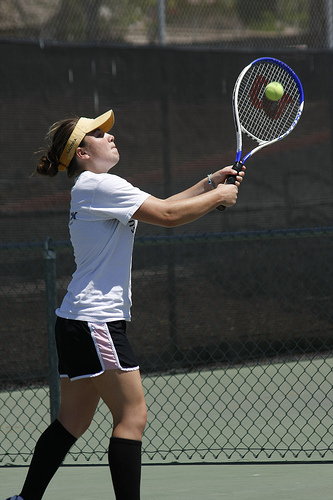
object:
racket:
[215, 56, 305, 212]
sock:
[104, 435, 143, 499]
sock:
[16, 416, 78, 495]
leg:
[91, 350, 148, 500]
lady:
[2, 109, 247, 500]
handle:
[216, 161, 243, 211]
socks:
[19, 417, 142, 499]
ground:
[0, 0, 333, 500]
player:
[8, 109, 246, 500]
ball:
[264, 79, 284, 101]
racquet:
[215, 55, 304, 213]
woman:
[3, 108, 247, 500]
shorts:
[53, 312, 142, 383]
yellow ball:
[264, 79, 285, 102]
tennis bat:
[215, 53, 308, 212]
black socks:
[106, 432, 142, 497]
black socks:
[19, 419, 76, 500]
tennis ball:
[264, 79, 285, 102]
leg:
[88, 346, 148, 500]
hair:
[35, 116, 78, 180]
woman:
[0, 118, 246, 500]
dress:
[53, 169, 150, 382]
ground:
[0, 349, 330, 497]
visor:
[57, 108, 114, 173]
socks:
[106, 433, 143, 499]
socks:
[14, 418, 76, 500]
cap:
[57, 108, 115, 171]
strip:
[85, 320, 123, 373]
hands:
[214, 164, 246, 209]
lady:
[6, 108, 246, 500]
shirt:
[54, 169, 152, 322]